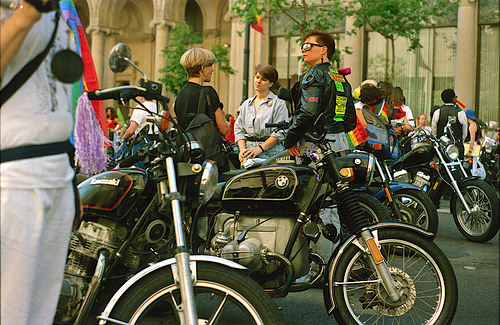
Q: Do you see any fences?
A: No, there are no fences.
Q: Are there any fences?
A: No, there are no fences.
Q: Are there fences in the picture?
A: No, there are no fences.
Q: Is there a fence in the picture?
A: No, there are no fences.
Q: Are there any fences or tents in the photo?
A: No, there are no fences or tents.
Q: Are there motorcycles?
A: Yes, there is a motorcycle.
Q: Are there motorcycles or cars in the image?
A: Yes, there is a motorcycle.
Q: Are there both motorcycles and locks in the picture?
A: No, there is a motorcycle but no locks.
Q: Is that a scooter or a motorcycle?
A: That is a motorcycle.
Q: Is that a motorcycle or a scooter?
A: That is a motorcycle.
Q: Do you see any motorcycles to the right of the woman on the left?
A: Yes, there is a motorcycle to the right of the woman.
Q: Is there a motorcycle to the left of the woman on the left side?
A: No, the motorcycle is to the right of the woman.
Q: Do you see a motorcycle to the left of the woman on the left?
A: No, the motorcycle is to the right of the woman.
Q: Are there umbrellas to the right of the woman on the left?
A: No, there is a motorcycle to the right of the woman.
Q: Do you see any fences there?
A: No, there are no fences.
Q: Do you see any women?
A: Yes, there is a woman.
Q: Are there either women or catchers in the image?
A: Yes, there is a woman.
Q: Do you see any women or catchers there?
A: Yes, there is a woman.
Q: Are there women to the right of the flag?
A: Yes, there is a woman to the right of the flag.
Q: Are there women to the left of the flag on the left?
A: No, the woman is to the right of the flag.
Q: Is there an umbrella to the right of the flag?
A: No, there is a woman to the right of the flag.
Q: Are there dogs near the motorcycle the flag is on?
A: No, there is a woman near the motorcycle.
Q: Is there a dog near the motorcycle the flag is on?
A: No, there is a woman near the motorcycle.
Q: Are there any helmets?
A: No, there are no helmets.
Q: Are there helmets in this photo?
A: No, there are no helmets.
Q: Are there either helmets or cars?
A: No, there are no helmets or cars.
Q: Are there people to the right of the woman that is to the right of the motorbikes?
A: Yes, there is a person to the right of the woman.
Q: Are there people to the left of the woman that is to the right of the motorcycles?
A: No, the person is to the right of the woman.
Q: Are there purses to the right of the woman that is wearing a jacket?
A: No, there is a person to the right of the woman.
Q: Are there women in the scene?
A: Yes, there is a woman.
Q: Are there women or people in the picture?
A: Yes, there is a woman.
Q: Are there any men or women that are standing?
A: Yes, the woman is standing.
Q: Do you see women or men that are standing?
A: Yes, the woman is standing.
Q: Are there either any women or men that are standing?
A: Yes, the woman is standing.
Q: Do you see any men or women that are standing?
A: Yes, the woman is standing.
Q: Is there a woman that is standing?
A: Yes, there is a woman that is standing.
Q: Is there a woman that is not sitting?
A: Yes, there is a woman that is standing.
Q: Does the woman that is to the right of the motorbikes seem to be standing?
A: Yes, the woman is standing.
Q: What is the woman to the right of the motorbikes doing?
A: The woman is standing.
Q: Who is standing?
A: The woman is standing.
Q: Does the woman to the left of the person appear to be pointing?
A: No, the woman is standing.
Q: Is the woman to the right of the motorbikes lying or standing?
A: The woman is standing.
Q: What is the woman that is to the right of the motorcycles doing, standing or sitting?
A: The woman is standing.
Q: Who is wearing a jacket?
A: The woman is wearing a jacket.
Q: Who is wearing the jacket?
A: The woman is wearing a jacket.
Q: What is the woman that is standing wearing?
A: The woman is wearing a jacket.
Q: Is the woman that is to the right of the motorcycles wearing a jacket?
A: Yes, the woman is wearing a jacket.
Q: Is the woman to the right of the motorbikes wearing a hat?
A: No, the woman is wearing a jacket.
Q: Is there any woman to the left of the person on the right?
A: Yes, there is a woman to the left of the person.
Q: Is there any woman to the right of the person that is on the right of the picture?
A: No, the woman is to the left of the person.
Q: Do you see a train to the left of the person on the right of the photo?
A: No, there is a woman to the left of the person.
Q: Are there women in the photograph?
A: Yes, there is a woman.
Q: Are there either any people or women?
A: Yes, there is a woman.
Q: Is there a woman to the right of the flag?
A: Yes, there is a woman to the right of the flag.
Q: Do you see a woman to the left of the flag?
A: No, the woman is to the right of the flag.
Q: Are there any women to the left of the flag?
A: No, the woman is to the right of the flag.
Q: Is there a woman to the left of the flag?
A: No, the woman is to the right of the flag.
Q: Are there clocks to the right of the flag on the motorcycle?
A: No, there is a woman to the right of the flag.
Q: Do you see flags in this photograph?
A: Yes, there is a flag.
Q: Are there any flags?
A: Yes, there is a flag.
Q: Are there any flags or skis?
A: Yes, there is a flag.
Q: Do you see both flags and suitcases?
A: No, there is a flag but no suitcases.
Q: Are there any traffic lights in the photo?
A: No, there are no traffic lights.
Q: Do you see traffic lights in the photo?
A: No, there are no traffic lights.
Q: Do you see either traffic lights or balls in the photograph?
A: No, there are no traffic lights or balls.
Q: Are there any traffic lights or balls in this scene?
A: No, there are no traffic lights or balls.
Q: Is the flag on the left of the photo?
A: Yes, the flag is on the left of the image.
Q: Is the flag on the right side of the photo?
A: No, the flag is on the left of the image.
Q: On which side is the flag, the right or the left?
A: The flag is on the left of the image.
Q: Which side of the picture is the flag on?
A: The flag is on the left of the image.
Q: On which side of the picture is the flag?
A: The flag is on the left of the image.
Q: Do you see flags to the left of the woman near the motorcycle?
A: Yes, there is a flag to the left of the woman.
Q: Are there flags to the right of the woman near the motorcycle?
A: No, the flag is to the left of the woman.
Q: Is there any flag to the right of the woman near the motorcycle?
A: No, the flag is to the left of the woman.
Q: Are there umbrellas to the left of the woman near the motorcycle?
A: No, there is a flag to the left of the woman.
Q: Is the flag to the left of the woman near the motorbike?
A: Yes, the flag is to the left of the woman.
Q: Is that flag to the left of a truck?
A: No, the flag is to the left of the woman.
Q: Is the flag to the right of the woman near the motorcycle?
A: No, the flag is to the left of the woman.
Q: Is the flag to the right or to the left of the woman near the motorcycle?
A: The flag is to the left of the woman.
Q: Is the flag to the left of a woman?
A: Yes, the flag is to the left of a woman.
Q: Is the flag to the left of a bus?
A: No, the flag is to the left of a woman.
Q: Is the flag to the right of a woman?
A: No, the flag is to the left of a woman.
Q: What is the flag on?
A: The flag is on the motorbike.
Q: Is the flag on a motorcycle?
A: Yes, the flag is on a motorcycle.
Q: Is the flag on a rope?
A: No, the flag is on a motorcycle.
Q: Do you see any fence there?
A: No, there are no fences.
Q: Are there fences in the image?
A: No, there are no fences.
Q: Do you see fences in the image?
A: No, there are no fences.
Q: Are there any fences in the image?
A: No, there are no fences.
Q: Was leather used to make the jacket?
A: Yes, the jacket is made of leather.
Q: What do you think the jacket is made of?
A: The jacket is made of leather.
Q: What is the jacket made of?
A: The jacket is made of leather.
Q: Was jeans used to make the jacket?
A: No, the jacket is made of leather.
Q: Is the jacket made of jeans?
A: No, the jacket is made of leather.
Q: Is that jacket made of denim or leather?
A: The jacket is made of leather.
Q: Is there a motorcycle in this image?
A: Yes, there is a motorcycle.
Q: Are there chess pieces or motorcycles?
A: Yes, there is a motorcycle.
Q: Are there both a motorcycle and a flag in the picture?
A: Yes, there are both a motorcycle and a flag.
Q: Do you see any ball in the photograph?
A: No, there are no balls.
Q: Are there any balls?
A: No, there are no balls.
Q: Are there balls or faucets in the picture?
A: No, there are no balls or faucets.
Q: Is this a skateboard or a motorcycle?
A: This is a motorcycle.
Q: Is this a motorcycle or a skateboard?
A: This is a motorcycle.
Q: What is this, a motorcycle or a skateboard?
A: This is a motorcycle.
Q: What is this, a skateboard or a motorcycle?
A: This is a motorcycle.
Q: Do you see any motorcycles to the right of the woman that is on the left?
A: Yes, there is a motorcycle to the right of the woman.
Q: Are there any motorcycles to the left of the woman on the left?
A: No, the motorcycle is to the right of the woman.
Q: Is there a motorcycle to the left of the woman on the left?
A: No, the motorcycle is to the right of the woman.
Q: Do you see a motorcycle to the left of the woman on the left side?
A: No, the motorcycle is to the right of the woman.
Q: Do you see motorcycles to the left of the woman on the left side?
A: No, the motorcycle is to the right of the woman.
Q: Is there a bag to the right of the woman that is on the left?
A: No, there is a motorcycle to the right of the woman.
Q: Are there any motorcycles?
A: Yes, there are motorcycles.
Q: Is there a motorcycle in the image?
A: Yes, there are motorcycles.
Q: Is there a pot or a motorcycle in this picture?
A: Yes, there are motorcycles.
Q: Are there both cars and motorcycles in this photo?
A: No, there are motorcycles but no cars.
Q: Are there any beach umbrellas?
A: No, there are no beach umbrellas.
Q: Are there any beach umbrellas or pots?
A: No, there are no beach umbrellas or pots.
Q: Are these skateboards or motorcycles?
A: These are motorcycles.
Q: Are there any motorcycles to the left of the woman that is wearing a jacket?
A: Yes, there are motorcycles to the left of the woman.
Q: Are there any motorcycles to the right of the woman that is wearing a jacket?
A: No, the motorcycles are to the left of the woman.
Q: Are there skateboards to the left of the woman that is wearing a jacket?
A: No, there are motorcycles to the left of the woman.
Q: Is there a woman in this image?
A: Yes, there is a woman.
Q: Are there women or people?
A: Yes, there is a woman.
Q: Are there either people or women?
A: Yes, there is a woman.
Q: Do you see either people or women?
A: Yes, there is a woman.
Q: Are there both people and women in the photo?
A: Yes, there are both a woman and a person.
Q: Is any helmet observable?
A: No, there are no helmets.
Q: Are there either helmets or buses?
A: No, there are no helmets or buses.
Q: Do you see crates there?
A: No, there are no crates.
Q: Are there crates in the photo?
A: No, there are no crates.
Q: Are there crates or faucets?
A: No, there are no crates or faucets.